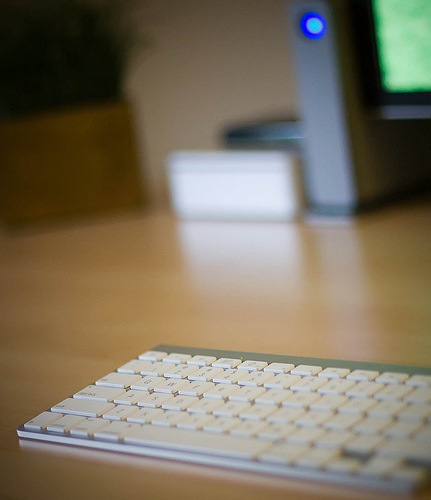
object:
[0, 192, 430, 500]
table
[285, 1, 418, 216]
computer tower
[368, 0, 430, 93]
screen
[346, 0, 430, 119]
computer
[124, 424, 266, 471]
spacebar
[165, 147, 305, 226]
square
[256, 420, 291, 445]
keyboard keys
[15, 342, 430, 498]
keyboard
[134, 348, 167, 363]
key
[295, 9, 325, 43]
light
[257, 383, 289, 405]
key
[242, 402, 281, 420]
key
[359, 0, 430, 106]
monitor